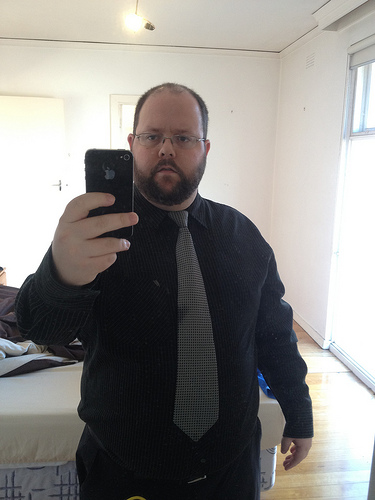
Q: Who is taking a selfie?
A: A man.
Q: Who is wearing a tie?
A: A man.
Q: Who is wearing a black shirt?
A: A man.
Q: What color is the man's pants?
A: Black.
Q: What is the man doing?
A: Taking a selfie.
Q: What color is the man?
A: White.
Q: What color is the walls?
A: White.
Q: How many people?
A: One.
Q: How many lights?
A: One.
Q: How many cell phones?
A: One.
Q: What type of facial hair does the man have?
A: Beard.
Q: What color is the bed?
A: White.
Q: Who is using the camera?
A: The man.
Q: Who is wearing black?
A: The man.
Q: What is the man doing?
A: Taking selfie.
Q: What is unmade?
A: Bed.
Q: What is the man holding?
A: Phone.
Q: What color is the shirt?
A: Black.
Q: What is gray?
A: Tie.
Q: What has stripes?
A: Shirt.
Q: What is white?
A: Sheets.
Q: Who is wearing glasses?
A: The man.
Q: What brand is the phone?
A: Apple.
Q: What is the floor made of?
A: Wood.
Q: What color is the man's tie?
A: Grey.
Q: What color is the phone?
A: Black.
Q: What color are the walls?
A: White.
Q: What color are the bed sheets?
A: Grey.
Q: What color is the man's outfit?
A: Black.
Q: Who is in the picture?
A: A white man.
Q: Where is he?
A: In the bedroom.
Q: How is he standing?
A: Upright.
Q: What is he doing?
A: He is taking a photo.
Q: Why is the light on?
A: The room is dark.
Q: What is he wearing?
A: A black shirt.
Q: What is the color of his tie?
A: Grey.